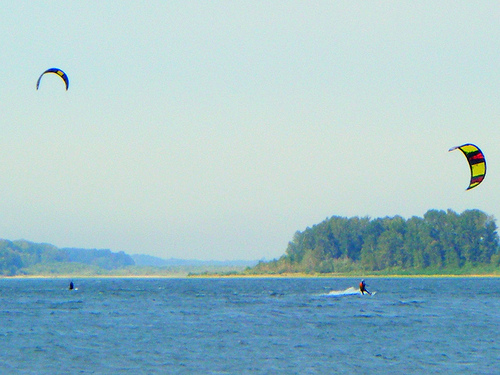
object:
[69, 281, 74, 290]
boarder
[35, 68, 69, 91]
kite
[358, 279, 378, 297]
boarder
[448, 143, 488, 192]
kite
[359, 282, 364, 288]
vest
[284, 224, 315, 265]
tree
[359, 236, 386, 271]
tree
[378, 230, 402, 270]
tree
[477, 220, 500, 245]
tree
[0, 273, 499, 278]
shoreline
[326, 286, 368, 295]
wake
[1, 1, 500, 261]
sky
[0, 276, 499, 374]
lake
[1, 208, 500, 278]
distance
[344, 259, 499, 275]
vegetation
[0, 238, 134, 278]
mountain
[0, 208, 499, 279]
island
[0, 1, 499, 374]
outside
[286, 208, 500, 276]
patch